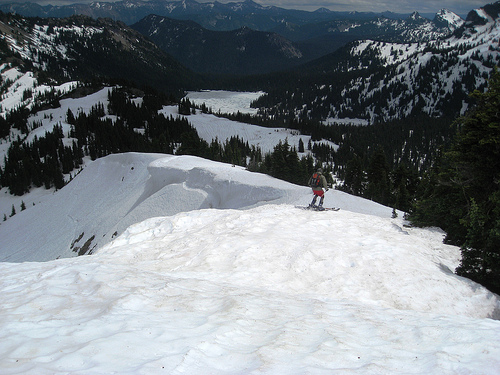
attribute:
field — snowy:
[189, 64, 377, 165]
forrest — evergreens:
[2, 0, 498, 297]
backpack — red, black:
[306, 169, 328, 190]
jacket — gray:
[312, 171, 331, 197]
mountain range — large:
[4, 1, 481, 226]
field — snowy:
[92, 174, 457, 374]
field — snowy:
[127, 196, 463, 371]